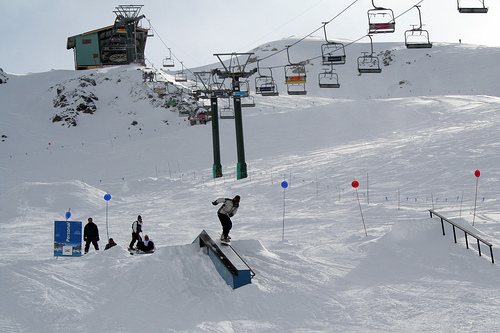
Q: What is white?
A: Snow.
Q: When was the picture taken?
A: Daytime.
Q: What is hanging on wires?
A: Chairs.